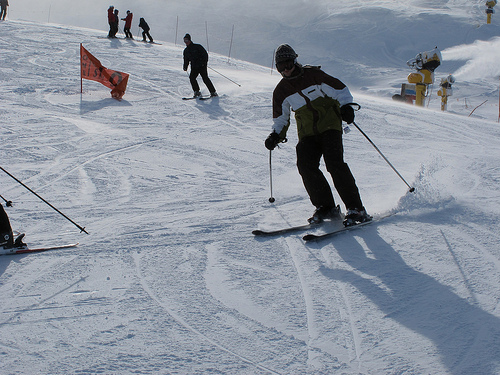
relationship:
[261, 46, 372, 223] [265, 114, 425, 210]
man has skis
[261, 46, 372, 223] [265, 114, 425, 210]
man holds skis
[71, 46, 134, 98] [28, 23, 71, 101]
flag on hill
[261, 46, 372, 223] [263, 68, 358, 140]
man wears jacket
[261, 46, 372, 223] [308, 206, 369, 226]
man wears snow boots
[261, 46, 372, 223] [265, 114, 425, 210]
man leans on skis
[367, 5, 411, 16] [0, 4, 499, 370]
jackson mingus responsible for photo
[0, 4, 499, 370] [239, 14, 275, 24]
photo has alot of detail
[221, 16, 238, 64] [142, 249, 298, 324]
pole in snow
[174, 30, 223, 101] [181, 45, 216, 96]
skier wears black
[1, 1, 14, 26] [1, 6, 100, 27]
lone skier in distance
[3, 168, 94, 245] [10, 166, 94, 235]
back of ski pole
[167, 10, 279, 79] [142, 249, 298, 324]
rods stick out of snow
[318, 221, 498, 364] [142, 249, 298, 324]
shadow in snow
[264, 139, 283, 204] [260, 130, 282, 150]
ski pole in hand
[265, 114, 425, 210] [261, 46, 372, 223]
skis used by man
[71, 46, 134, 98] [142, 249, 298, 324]
flag in snow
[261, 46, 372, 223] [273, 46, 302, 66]
man has hat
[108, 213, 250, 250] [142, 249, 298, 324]
ski tracks are in snow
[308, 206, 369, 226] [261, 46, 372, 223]
snow boots are on man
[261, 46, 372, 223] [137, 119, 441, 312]
man skiing on slope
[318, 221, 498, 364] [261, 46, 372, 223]
shadow of a man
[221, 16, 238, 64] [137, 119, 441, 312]
pole on slope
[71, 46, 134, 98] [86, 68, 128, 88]
flag has writing